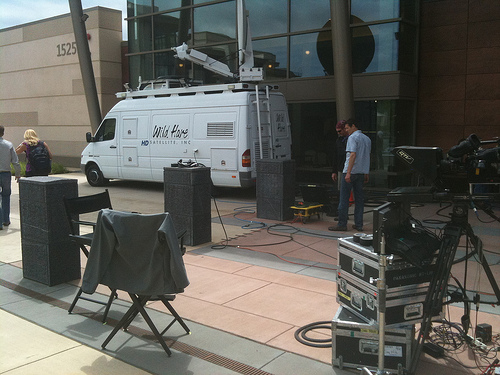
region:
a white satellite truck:
[79, 80, 301, 200]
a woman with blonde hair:
[13, 123, 57, 175]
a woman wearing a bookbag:
[13, 125, 58, 172]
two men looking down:
[328, 118, 373, 228]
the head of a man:
[342, 117, 356, 134]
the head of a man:
[334, 118, 343, 138]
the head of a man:
[1, 122, 8, 142]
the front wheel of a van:
[81, 160, 106, 185]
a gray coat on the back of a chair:
[76, 204, 189, 299]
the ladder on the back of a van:
[250, 80, 277, 152]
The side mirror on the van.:
[87, 130, 94, 142]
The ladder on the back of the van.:
[253, 84, 275, 158]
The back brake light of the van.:
[242, 149, 249, 169]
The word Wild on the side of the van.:
[152, 123, 169, 136]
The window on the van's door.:
[94, 120, 118, 142]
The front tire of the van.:
[83, 163, 102, 187]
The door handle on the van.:
[110, 143, 117, 150]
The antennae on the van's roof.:
[161, 1, 263, 82]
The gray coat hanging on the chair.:
[85, 204, 186, 301]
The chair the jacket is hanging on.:
[89, 212, 186, 349]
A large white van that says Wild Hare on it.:
[80, 80, 293, 188]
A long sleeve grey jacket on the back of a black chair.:
[81, 208, 190, 296]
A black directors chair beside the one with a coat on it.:
[62, 187, 128, 324]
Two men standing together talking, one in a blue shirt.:
[328, 119, 373, 233]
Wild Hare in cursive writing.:
[150, 123, 188, 139]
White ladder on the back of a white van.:
[253, 82, 276, 162]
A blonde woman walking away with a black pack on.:
[15, 126, 53, 177]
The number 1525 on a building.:
[53, 42, 78, 57]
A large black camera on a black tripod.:
[389, 133, 499, 371]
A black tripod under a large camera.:
[411, 200, 498, 371]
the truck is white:
[85, 63, 282, 255]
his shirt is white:
[333, 127, 384, 164]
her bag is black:
[10, 137, 55, 192]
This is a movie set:
[14, 125, 494, 342]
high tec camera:
[390, 129, 487, 265]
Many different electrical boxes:
[319, 223, 422, 374]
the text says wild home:
[146, 115, 201, 152]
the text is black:
[140, 105, 202, 165]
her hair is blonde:
[25, 123, 41, 148]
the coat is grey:
[100, 215, 175, 302]